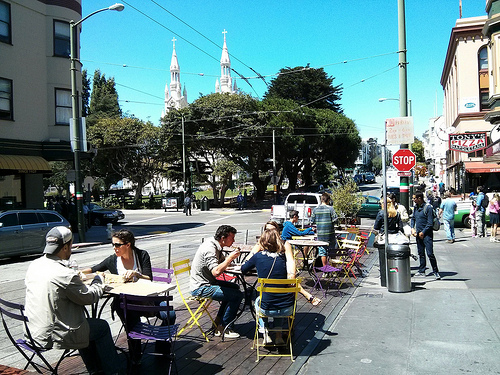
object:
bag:
[386, 250, 418, 261]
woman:
[77, 229, 154, 283]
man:
[188, 224, 245, 340]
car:
[0, 210, 73, 260]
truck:
[270, 192, 333, 231]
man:
[410, 190, 442, 280]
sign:
[392, 148, 417, 172]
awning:
[464, 161, 500, 175]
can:
[387, 242, 411, 293]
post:
[382, 120, 390, 289]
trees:
[155, 91, 263, 211]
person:
[239, 229, 297, 348]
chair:
[308, 247, 348, 299]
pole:
[68, 19, 87, 243]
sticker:
[389, 266, 398, 274]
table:
[287, 239, 329, 291]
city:
[2, 0, 500, 375]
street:
[292, 219, 499, 375]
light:
[104, 2, 128, 12]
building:
[419, 11, 500, 211]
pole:
[396, 0, 416, 236]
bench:
[126, 197, 162, 210]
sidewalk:
[114, 202, 244, 214]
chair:
[250, 277, 302, 363]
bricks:
[265, 354, 298, 374]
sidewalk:
[0, 220, 500, 375]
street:
[116, 204, 276, 228]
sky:
[83, 0, 459, 156]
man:
[21, 224, 121, 375]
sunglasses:
[111, 242, 127, 248]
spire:
[162, 32, 188, 119]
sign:
[448, 131, 488, 154]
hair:
[214, 223, 238, 240]